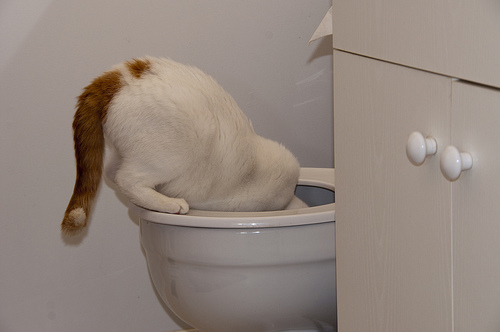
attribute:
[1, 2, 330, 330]
bathroom wall — white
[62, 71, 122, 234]
tail — brown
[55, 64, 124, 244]
tail — brown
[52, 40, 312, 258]
cat — brown, white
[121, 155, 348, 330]
bowl — white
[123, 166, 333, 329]
toilet — white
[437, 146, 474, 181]
knob — white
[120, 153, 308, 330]
toilet — scene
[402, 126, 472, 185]
handles — white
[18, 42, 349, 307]
fur — white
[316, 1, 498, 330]
shelf — white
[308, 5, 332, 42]
toilet paper — white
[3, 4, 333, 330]
wall — white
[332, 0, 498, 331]
bathroom cabinet — white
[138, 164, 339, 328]
toilet — white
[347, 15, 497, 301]
caninet — wooden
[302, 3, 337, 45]
paper — brown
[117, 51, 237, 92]
back — cat's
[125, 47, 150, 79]
patch — brown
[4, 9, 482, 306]
bathroom — white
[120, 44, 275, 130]
back — white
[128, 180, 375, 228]
seat — white